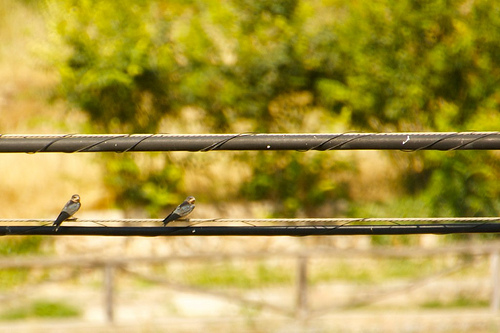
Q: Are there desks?
A: No, there are no desks.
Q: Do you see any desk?
A: No, there are no desks.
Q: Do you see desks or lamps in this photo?
A: No, there are no desks or lamps.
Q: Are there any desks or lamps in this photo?
A: No, there are no desks or lamps.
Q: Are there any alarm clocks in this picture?
A: No, there are no alarm clocks.